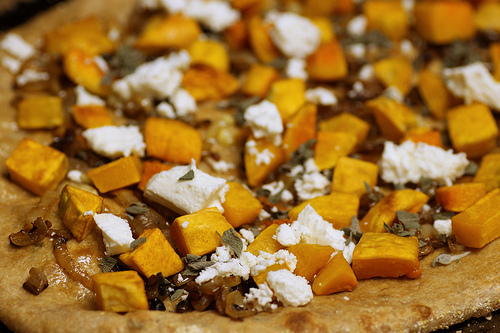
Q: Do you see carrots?
A: Yes, there is a carrot.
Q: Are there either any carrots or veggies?
A: Yes, there is a carrot.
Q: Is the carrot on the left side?
A: Yes, the carrot is on the left of the image.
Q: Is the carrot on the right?
A: No, the carrot is on the left of the image.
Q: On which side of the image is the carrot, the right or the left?
A: The carrot is on the left of the image.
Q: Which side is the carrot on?
A: The carrot is on the left of the image.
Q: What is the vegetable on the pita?
A: The vegetable is a carrot.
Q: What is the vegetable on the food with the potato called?
A: The vegetable is a carrot.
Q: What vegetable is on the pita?
A: The vegetable is a carrot.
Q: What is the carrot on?
A: The carrot is on the pita.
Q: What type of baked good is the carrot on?
A: The carrot is on the pita.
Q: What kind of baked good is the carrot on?
A: The carrot is on the pita.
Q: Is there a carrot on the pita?
A: Yes, there is a carrot on the pita.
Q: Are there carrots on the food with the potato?
A: Yes, there is a carrot on the pita.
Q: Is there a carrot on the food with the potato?
A: Yes, there is a carrot on the pita.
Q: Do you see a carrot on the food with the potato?
A: Yes, there is a carrot on the pita.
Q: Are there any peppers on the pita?
A: No, there is a carrot on the pita.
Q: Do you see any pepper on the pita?
A: No, there is a carrot on the pita.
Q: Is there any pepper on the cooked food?
A: No, there is a carrot on the pita.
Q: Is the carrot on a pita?
A: Yes, the carrot is on a pita.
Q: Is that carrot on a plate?
A: No, the carrot is on a pita.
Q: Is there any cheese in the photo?
A: Yes, there is cheese.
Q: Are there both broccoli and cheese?
A: No, there is cheese but no broccoli.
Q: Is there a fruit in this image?
A: No, there are no fruits.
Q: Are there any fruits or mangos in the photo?
A: No, there are no fruits or mangos.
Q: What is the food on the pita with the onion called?
A: The food is cheese.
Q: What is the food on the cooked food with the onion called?
A: The food is cheese.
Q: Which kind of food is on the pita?
A: The food is cheese.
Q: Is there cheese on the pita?
A: Yes, there is cheese on the pita.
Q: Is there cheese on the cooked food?
A: Yes, there is cheese on the pita.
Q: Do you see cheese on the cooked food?
A: Yes, there is cheese on the pita.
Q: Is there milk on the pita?
A: No, there is cheese on the pita.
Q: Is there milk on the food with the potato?
A: No, there is cheese on the pita.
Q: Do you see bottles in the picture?
A: No, there are no bottles.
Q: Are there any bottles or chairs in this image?
A: No, there are no bottles or chairs.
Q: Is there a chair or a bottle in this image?
A: No, there are no bottles or chairs.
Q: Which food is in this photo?
A: The food is a pita.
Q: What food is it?
A: The food is a pita.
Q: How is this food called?
A: This is a pita.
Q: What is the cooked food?
A: The food is a pita.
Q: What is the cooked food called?
A: The food is a pita.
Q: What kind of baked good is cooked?
A: The baked good is a pita.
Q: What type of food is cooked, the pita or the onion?
A: The pita is cooked.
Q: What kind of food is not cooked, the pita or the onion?
A: The onion is not cooked.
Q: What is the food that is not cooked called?
A: The food is an onion.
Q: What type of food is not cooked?
A: The food is an onion.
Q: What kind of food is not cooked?
A: The food is an onion.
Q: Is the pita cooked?
A: Yes, the pita is cooked.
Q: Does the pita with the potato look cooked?
A: Yes, the pita is cooked.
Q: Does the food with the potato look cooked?
A: Yes, the pita is cooked.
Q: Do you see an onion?
A: Yes, there is an onion.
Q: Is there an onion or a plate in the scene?
A: Yes, there is an onion.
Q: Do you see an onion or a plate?
A: Yes, there is an onion.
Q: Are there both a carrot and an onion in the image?
A: Yes, there are both an onion and a carrot.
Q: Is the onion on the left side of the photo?
A: Yes, the onion is on the left of the image.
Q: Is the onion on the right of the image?
A: No, the onion is on the left of the image.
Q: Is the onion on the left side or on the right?
A: The onion is on the left of the image.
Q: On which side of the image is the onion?
A: The onion is on the left of the image.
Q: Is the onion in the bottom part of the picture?
A: Yes, the onion is in the bottom of the image.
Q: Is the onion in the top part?
A: No, the onion is in the bottom of the image.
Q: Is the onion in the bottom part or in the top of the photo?
A: The onion is in the bottom of the image.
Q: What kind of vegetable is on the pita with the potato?
A: The vegetable is an onion.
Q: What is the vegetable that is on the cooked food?
A: The vegetable is an onion.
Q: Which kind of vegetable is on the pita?
A: The vegetable is an onion.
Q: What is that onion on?
A: The onion is on the pita.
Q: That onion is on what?
A: The onion is on the pita.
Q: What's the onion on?
A: The onion is on the pita.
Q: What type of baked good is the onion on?
A: The onion is on the pita.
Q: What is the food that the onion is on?
A: The food is a pita.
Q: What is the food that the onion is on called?
A: The food is a pita.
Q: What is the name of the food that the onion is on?
A: The food is a pita.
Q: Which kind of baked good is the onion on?
A: The onion is on the pita.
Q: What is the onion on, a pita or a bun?
A: The onion is on a pita.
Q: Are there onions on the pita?
A: Yes, there is an onion on the pita.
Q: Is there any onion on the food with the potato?
A: Yes, there is an onion on the pita.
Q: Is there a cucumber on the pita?
A: No, there is an onion on the pita.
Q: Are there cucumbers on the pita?
A: No, there is an onion on the pita.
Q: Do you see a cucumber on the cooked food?
A: No, there is an onion on the pita.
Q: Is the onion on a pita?
A: Yes, the onion is on a pita.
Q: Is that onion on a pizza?
A: No, the onion is on a pita.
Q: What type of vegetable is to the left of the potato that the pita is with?
A: The vegetable is an onion.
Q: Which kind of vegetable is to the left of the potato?
A: The vegetable is an onion.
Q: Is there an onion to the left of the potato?
A: Yes, there is an onion to the left of the potato.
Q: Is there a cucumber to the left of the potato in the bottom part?
A: No, there is an onion to the left of the potato.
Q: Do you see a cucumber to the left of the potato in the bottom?
A: No, there is an onion to the left of the potato.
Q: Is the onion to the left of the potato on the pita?
A: Yes, the onion is to the left of the potato.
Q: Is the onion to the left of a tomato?
A: No, the onion is to the left of the potato.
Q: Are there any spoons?
A: No, there are no spoons.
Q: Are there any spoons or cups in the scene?
A: No, there are no spoons or cups.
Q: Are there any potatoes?
A: Yes, there is a potato.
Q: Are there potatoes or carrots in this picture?
A: Yes, there is a potato.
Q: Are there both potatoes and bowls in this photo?
A: No, there is a potato but no bowls.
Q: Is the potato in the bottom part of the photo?
A: Yes, the potato is in the bottom of the image.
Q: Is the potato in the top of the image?
A: No, the potato is in the bottom of the image.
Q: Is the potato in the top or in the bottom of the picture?
A: The potato is in the bottom of the image.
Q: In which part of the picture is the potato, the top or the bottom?
A: The potato is in the bottom of the image.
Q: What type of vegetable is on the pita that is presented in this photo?
A: The vegetable is a potato.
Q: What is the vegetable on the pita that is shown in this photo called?
A: The vegetable is a potato.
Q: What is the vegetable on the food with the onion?
A: The vegetable is a potato.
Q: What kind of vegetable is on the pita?
A: The vegetable is a potato.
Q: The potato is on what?
A: The potato is on the pita.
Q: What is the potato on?
A: The potato is on the pita.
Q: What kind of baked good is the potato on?
A: The potato is on the pita.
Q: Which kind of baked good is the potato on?
A: The potato is on the pita.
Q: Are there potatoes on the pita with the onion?
A: Yes, there is a potato on the pita.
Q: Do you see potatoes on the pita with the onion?
A: Yes, there is a potato on the pita.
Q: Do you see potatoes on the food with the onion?
A: Yes, there is a potato on the pita.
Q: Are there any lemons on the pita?
A: No, there is a potato on the pita.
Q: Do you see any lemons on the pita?
A: No, there is a potato on the pita.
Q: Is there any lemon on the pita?
A: No, there is a potato on the pita.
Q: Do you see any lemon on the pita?
A: No, there is a potato on the pita.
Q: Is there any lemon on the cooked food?
A: No, there is a potato on the pita.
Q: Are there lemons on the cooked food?
A: No, there is a potato on the pita.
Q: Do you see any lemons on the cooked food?
A: No, there is a potato on the pita.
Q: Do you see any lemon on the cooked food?
A: No, there is a potato on the pita.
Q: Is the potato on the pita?
A: Yes, the potato is on the pita.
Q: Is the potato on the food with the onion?
A: Yes, the potato is on the pita.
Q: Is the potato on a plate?
A: No, the potato is on the pita.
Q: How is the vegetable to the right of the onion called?
A: The vegetable is a potato.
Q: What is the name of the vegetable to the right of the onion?
A: The vegetable is a potato.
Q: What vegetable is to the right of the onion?
A: The vegetable is a potato.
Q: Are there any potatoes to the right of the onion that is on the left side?
A: Yes, there is a potato to the right of the onion.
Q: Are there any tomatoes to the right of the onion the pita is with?
A: No, there is a potato to the right of the onion.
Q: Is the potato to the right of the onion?
A: Yes, the potato is to the right of the onion.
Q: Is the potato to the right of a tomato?
A: No, the potato is to the right of the onion.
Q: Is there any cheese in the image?
A: Yes, there is cheese.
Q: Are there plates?
A: No, there are no plates.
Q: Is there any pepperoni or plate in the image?
A: No, there are no plates or pepperoni.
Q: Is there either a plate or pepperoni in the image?
A: No, there are no plates or pepperoni.